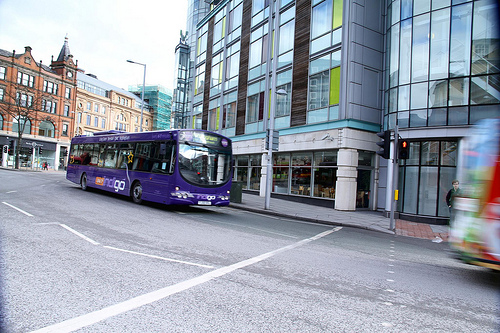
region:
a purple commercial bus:
[69, 130, 253, 219]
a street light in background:
[376, 118, 416, 245]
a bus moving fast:
[435, 97, 498, 276]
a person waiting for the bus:
[432, 163, 487, 246]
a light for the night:
[113, 43, 205, 121]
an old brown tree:
[7, 91, 49, 173]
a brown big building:
[4, 43, 160, 193]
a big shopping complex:
[176, 18, 463, 242]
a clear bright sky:
[15, 8, 187, 91]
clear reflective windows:
[374, 30, 498, 117]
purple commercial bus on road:
[66, 124, 253, 221]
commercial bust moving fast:
[437, 111, 495, 276]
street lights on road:
[370, 132, 429, 243]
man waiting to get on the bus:
[432, 173, 480, 242]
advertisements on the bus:
[84, 166, 145, 206]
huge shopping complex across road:
[191, 18, 477, 220]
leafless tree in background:
[8, 94, 54, 169]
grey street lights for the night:
[105, 51, 192, 122]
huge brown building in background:
[5, 36, 147, 176]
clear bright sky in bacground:
[27, 11, 173, 62]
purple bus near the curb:
[69, 131, 232, 206]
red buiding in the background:
[0, 33, 150, 175]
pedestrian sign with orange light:
[398, 139, 408, 161]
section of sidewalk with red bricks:
[395, 218, 448, 241]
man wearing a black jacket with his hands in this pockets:
[446, 178, 459, 211]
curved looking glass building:
[380, 2, 497, 227]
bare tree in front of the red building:
[4, 79, 50, 170]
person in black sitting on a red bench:
[41, 161, 49, 170]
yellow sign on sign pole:
[394, 188, 398, 199]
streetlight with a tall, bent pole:
[125, 58, 146, 128]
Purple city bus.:
[67, 128, 246, 209]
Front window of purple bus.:
[178, 138, 235, 191]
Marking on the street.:
[48, 211, 400, 319]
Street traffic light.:
[379, 132, 411, 169]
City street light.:
[118, 49, 151, 94]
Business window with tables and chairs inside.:
[274, 166, 342, 201]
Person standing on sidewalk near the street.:
[442, 172, 467, 239]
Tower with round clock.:
[46, 26, 86, 86]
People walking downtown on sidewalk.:
[37, 151, 50, 178]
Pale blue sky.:
[67, 6, 169, 51]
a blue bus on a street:
[67, 121, 239, 212]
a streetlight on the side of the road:
[374, 125, 416, 232]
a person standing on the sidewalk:
[446, 171, 466, 234]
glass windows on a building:
[381, 5, 496, 122]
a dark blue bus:
[70, 128, 241, 210]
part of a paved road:
[3, 172, 63, 328]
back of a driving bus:
[460, 113, 496, 291]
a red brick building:
[1, 33, 74, 135]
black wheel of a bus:
[127, 178, 157, 204]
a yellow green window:
[326, 63, 343, 108]